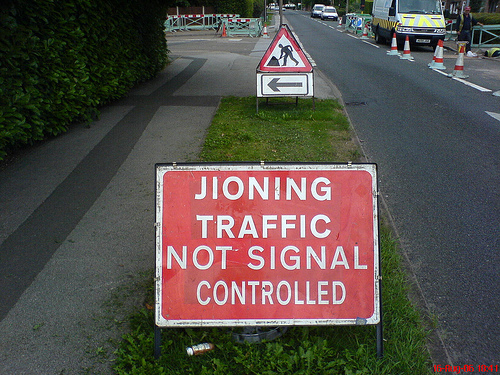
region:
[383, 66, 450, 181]
The street is made asphalt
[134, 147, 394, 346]
The sign in the middle of the road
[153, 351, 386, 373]
The grass is short and green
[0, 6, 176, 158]
The bushes are well manicured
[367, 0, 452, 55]
The van parked on the street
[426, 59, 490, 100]
The line in the middle of the street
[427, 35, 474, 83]
The traffic cones are white and orange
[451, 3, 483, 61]
The man standing by the hole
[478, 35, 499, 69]
The man in the hole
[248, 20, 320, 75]
The sign has a triangle shape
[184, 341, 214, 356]
a small bottle on the ground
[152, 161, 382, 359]
a red metal sign in the ground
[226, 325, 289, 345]
a hubcap on the ground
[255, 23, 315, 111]
a construction sign on the ground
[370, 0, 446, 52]
a van parked across the street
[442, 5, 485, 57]
a construction worker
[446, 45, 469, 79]
a safety cone in the street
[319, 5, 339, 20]
a car parked across the street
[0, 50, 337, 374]
a gray sidewalk and street corner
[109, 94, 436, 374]
a roadside patch of grass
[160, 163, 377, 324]
sign saying jioning traffic not signal controlled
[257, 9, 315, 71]
sign with man shoveling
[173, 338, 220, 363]
garbage in the grass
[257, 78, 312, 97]
arrow pointing left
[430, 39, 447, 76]
red and white cones in the road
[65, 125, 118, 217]
black strip on the road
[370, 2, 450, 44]
yellow and white van parked on the road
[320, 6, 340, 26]
white car parked on the road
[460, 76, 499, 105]
white lines on the road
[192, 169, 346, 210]
word jioning on the sign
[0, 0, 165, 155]
bushes on the side of the street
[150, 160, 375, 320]
a sign in the street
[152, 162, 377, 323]
The sign in the street is red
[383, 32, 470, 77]
cones in the street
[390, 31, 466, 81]
The cones are white and orange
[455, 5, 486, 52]
a person walking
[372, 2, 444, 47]
a van on the side of the road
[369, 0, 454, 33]
the van is yellow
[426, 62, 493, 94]
white line on the street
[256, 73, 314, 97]
arrow sign in the middle of the street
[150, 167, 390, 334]
red and white traffic sign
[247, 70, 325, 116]
black and white sign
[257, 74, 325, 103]
arrow is pointing left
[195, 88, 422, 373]
green grass in boulevard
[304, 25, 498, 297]
grey road next to signs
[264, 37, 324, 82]
red black and white men working sign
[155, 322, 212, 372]
small bottle under sign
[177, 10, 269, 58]
red and white stripes on fence in distance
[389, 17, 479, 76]
orange and white traffic cones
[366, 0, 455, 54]
yellow and white truck behind cones